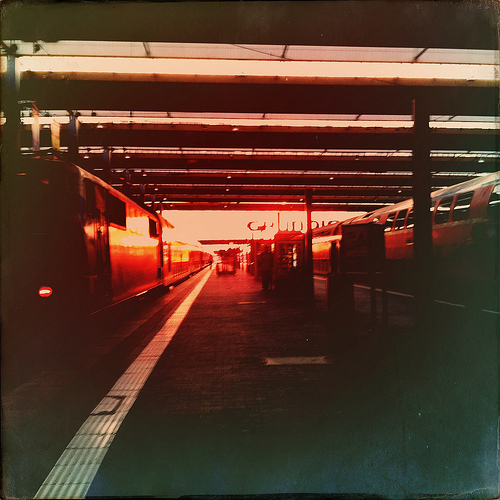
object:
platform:
[0, 263, 499, 499]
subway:
[0, 154, 213, 342]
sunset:
[130, 215, 330, 295]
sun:
[121, 217, 197, 251]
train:
[312, 170, 499, 310]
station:
[0, 0, 499, 497]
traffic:
[22, 150, 490, 331]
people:
[257, 246, 272, 291]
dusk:
[115, 199, 342, 299]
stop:
[40, 143, 496, 461]